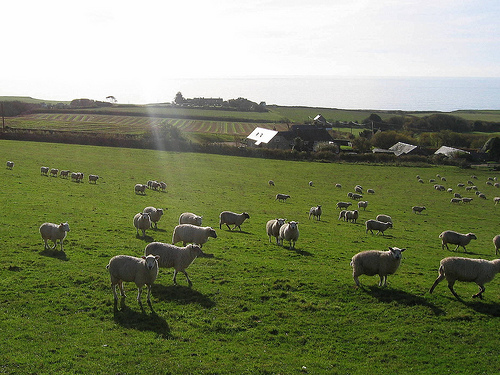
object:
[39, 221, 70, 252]
sheep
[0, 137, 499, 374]
pasture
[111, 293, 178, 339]
shadow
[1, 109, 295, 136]
field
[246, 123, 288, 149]
building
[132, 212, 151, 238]
sheep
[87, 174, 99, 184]
sheep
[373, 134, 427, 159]
buildings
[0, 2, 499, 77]
sky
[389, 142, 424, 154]
roofs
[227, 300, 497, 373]
grass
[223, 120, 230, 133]
crop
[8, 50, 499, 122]
background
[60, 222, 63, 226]
ear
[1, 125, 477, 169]
border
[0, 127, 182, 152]
shrubbery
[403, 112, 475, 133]
trees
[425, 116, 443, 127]
leaves